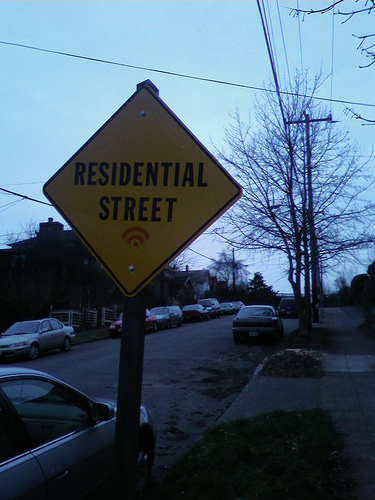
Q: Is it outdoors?
A: Yes, it is outdoors.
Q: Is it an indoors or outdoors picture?
A: It is outdoors.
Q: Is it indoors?
A: No, it is outdoors.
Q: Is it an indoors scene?
A: No, it is outdoors.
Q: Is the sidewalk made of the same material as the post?
A: No, the sidewalk is made of concrete and the post is made of wood.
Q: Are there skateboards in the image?
A: No, there are no skateboards.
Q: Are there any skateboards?
A: No, there are no skateboards.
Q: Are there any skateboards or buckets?
A: No, there are no skateboards or buckets.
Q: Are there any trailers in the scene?
A: No, there are no trailers.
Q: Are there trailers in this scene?
A: No, there are no trailers.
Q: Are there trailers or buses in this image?
A: No, there are no trailers or buses.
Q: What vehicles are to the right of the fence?
A: The vehicles are cars.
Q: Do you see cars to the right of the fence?
A: Yes, there are cars to the right of the fence.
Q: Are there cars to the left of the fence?
A: No, the cars are to the right of the fence.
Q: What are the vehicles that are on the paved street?
A: The vehicles are cars.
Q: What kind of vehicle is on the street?
A: The vehicles are cars.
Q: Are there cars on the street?
A: Yes, there are cars on the street.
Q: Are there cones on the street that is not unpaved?
A: No, there are cars on the street.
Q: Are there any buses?
A: No, there are no buses.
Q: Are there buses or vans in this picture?
A: No, there are no buses or vans.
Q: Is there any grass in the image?
A: Yes, there is grass.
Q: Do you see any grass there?
A: Yes, there is grass.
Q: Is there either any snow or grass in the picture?
A: Yes, there is grass.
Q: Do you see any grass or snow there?
A: Yes, there is grass.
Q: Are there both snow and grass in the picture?
A: No, there is grass but no snow.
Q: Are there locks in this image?
A: No, there are no locks.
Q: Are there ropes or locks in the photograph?
A: No, there are no locks or ropes.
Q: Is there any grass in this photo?
A: Yes, there is grass.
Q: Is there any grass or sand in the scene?
A: Yes, there is grass.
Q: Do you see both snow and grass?
A: No, there is grass but no snow.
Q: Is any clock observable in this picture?
A: No, there are no clocks.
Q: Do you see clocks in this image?
A: No, there are no clocks.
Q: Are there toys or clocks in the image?
A: No, there are no clocks or toys.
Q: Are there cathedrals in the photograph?
A: No, there are no cathedrals.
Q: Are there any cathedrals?
A: No, there are no cathedrals.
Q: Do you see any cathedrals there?
A: No, there are no cathedrals.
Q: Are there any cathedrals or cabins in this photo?
A: No, there are no cathedrals or cabins.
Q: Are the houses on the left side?
A: Yes, the houses are on the left of the image.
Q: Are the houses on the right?
A: No, the houses are on the left of the image.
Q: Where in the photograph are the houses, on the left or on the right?
A: The houses are on the left of the image.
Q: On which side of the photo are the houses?
A: The houses are on the left of the image.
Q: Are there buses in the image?
A: No, there are no buses.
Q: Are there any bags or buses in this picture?
A: No, there are no buses or bags.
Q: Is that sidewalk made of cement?
A: Yes, the sidewalk is made of cement.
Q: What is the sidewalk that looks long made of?
A: The sidewalk is made of concrete.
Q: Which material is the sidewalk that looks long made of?
A: The sidewalk is made of concrete.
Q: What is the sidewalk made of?
A: The sidewalk is made of concrete.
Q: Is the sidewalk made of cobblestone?
A: No, the sidewalk is made of concrete.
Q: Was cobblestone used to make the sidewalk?
A: No, the sidewalk is made of concrete.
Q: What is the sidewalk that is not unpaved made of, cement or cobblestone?
A: The sidewalk is made of cement.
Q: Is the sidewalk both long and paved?
A: Yes, the sidewalk is long and paved.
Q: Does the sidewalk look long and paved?
A: Yes, the sidewalk is long and paved.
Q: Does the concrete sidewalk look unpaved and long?
A: No, the side walk is long but paved.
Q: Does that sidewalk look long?
A: Yes, the sidewalk is long.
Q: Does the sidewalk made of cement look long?
A: Yes, the sidewalk is long.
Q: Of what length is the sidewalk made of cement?
A: The side walk is long.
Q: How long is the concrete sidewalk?
A: The sidewalk is long.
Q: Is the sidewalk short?
A: No, the sidewalk is long.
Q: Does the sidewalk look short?
A: No, the sidewalk is long.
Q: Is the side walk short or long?
A: The side walk is long.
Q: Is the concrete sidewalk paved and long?
A: Yes, the sidewalk is paved and long.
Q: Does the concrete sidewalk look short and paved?
A: No, the sidewalk is paved but long.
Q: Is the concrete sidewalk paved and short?
A: No, the sidewalk is paved but long.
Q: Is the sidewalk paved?
A: Yes, the sidewalk is paved.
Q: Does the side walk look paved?
A: Yes, the side walk is paved.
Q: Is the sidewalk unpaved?
A: No, the sidewalk is paved.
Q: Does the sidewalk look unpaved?
A: No, the sidewalk is paved.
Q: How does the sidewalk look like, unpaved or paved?
A: The sidewalk is paved.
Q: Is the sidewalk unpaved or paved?
A: The sidewalk is paved.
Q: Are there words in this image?
A: Yes, there are words.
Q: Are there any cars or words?
A: Yes, there are words.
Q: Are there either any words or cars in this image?
A: Yes, there are words.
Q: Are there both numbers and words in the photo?
A: No, there are words but no numbers.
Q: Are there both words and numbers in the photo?
A: No, there are words but no numbers.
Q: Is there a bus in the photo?
A: No, there are no buses.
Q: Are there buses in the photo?
A: No, there are no buses.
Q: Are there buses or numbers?
A: No, there are no buses or numbers.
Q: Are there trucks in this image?
A: No, there are no trucks.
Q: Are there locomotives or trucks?
A: No, there are no trucks or locomotives.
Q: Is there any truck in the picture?
A: No, there are no trucks.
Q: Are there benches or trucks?
A: No, there are no trucks or benches.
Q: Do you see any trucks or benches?
A: No, there are no trucks or benches.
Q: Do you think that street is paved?
A: Yes, the street is paved.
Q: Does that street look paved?
A: Yes, the street is paved.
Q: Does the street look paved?
A: Yes, the street is paved.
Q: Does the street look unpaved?
A: No, the street is paved.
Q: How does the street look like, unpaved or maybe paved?
A: The street is paved.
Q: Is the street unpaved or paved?
A: The street is paved.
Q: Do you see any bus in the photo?
A: No, there are no buses.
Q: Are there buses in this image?
A: No, there are no buses.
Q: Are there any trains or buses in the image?
A: No, there are no buses or trains.